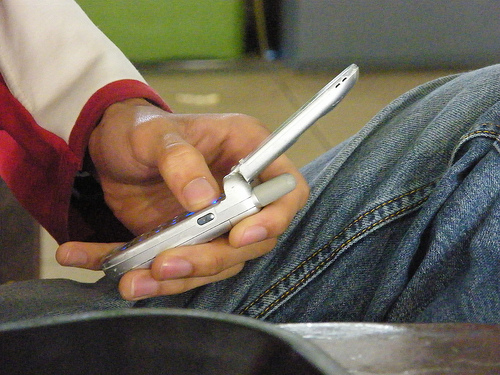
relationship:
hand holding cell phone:
[52, 96, 311, 304] [91, 65, 360, 280]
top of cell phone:
[227, 64, 362, 176] [91, 65, 360, 280]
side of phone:
[101, 196, 265, 273] [91, 65, 360, 280]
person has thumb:
[1, 2, 499, 320] [155, 143, 222, 211]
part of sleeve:
[47, 42, 104, 88] [2, 4, 170, 250]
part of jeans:
[373, 112, 406, 144] [133, 59, 500, 317]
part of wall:
[309, 11, 332, 33] [278, 4, 497, 67]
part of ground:
[221, 87, 238, 98] [148, 60, 452, 155]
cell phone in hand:
[91, 65, 360, 280] [52, 96, 311, 304]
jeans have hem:
[133, 59, 500, 317] [244, 180, 438, 330]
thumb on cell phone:
[155, 143, 222, 211] [91, 65, 360, 280]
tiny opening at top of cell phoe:
[332, 74, 342, 84] [91, 65, 360, 280]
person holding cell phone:
[1, 2, 499, 320] [91, 65, 360, 280]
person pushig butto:
[1, 2, 499, 320] [196, 199, 214, 212]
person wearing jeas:
[1, 2, 499, 320] [133, 59, 500, 317]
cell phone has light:
[91, 65, 360, 280] [103, 187, 225, 255]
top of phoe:
[227, 64, 362, 176] [91, 65, 360, 280]